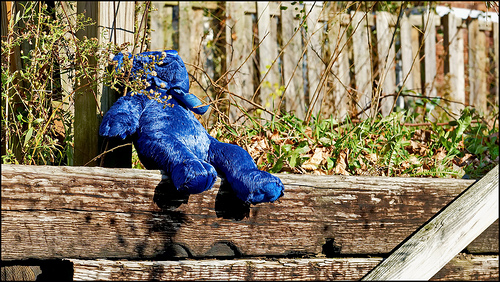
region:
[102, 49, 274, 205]
blue teddy bear on the wood log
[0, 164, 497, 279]
stacks of wood with a bear on it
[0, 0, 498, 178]
green plants growing by the fence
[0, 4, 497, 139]
small wooden fence by the wall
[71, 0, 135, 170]
wooden post with a bear leaning on it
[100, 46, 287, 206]
bear leaning against the wooden post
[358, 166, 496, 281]
small wooden beam next to the wall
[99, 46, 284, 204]
small blue bear left outside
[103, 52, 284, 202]
blue teddy bear next to the plants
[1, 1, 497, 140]
wooden fence behind the bear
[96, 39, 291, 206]
blue stuffed animal on fence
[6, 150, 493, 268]
wooden railway tie landscaping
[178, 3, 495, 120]
wooden slat fencing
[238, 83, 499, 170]
vegetation by wooden fence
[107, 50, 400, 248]
blue toy resting on wooden tie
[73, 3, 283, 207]
blue toy against fence post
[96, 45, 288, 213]
blue plush toy outside in sun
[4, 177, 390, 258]
wooden railway tie with cracks and wear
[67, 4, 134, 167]
unfinished wooden fence post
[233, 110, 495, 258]
green plants by railway tie landscaping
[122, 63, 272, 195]
A stuffed elephant on some wood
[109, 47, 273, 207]
The stuffed elephant is blue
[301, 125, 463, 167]
Plants behind the stuffed elephant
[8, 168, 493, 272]
Pieces of wood below the stuffed elephant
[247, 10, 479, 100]
A fence behind the blue elephant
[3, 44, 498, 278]
A blue elephant on pieces of wood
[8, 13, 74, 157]
Green plants by the blue elephant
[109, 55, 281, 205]
A stuffed elephant in front of a fence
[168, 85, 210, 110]
The trunk of the stuffed elephant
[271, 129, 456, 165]
Shrubbery by the fence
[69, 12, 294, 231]
a stuffed animal sitting on a ledge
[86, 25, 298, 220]
the stuffed animal is blue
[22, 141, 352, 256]
the ledge is brownish grey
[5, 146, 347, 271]
the ledge is made of wood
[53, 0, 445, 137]
a fence behind the stuffed animal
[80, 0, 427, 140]
the fence is made of wood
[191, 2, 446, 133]
the fence is grey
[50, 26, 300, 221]
the stuffed animal is a bear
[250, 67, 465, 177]
the grass is wild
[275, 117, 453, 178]
leaves are mixed in the grass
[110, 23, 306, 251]
the bear is blue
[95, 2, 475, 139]
fence made of wood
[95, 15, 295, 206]
bear sitting on wooden object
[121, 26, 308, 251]
sun shining on bear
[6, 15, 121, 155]
plant next to bear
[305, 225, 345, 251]
hole in the wood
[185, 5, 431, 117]
the fence is brown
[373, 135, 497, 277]
wooden stick laying on other wood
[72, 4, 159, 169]
wooden post on other wood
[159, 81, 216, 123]
ribbon tied on bear